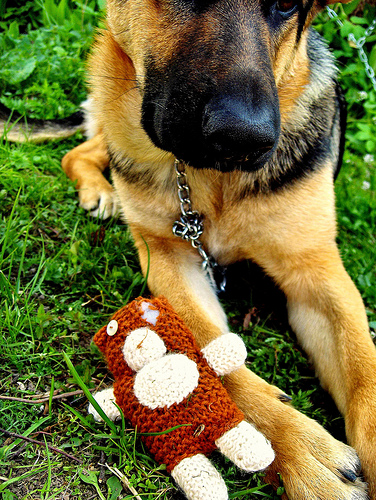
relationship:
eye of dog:
[274, 0, 299, 16] [60, 0, 373, 498]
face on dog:
[107, 1, 349, 168] [60, 0, 373, 498]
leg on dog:
[141, 239, 366, 495] [60, 0, 373, 498]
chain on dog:
[170, 154, 228, 293] [90, 0, 350, 330]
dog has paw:
[0, 0, 375, 499] [223, 380, 371, 498]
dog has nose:
[0, 0, 375, 499] [197, 98, 324, 169]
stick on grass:
[21, 382, 70, 413] [1, 337, 111, 479]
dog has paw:
[60, 0, 373, 498] [281, 417, 373, 498]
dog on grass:
[60, 0, 373, 498] [2, 3, 77, 113]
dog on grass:
[60, 0, 373, 498] [5, 151, 84, 404]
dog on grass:
[60, 0, 373, 498] [351, 99, 371, 282]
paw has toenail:
[288, 428, 372, 489] [330, 443, 368, 495]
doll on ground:
[66, 292, 294, 449] [19, 272, 299, 499]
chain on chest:
[170, 154, 228, 293] [146, 159, 302, 249]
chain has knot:
[170, 154, 228, 293] [165, 205, 210, 249]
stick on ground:
[0, 384, 96, 405] [3, 331, 172, 488]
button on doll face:
[104, 317, 121, 338] [82, 294, 193, 376]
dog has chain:
[60, 0, 373, 498] [169, 162, 225, 293]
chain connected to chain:
[328, 4, 375, 88] [170, 154, 228, 293]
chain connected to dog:
[328, 4, 375, 88] [60, 0, 373, 498]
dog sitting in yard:
[0, 0, 375, 499] [24, 95, 368, 402]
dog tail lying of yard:
[0, 99, 85, 144] [0, 0, 376, 498]